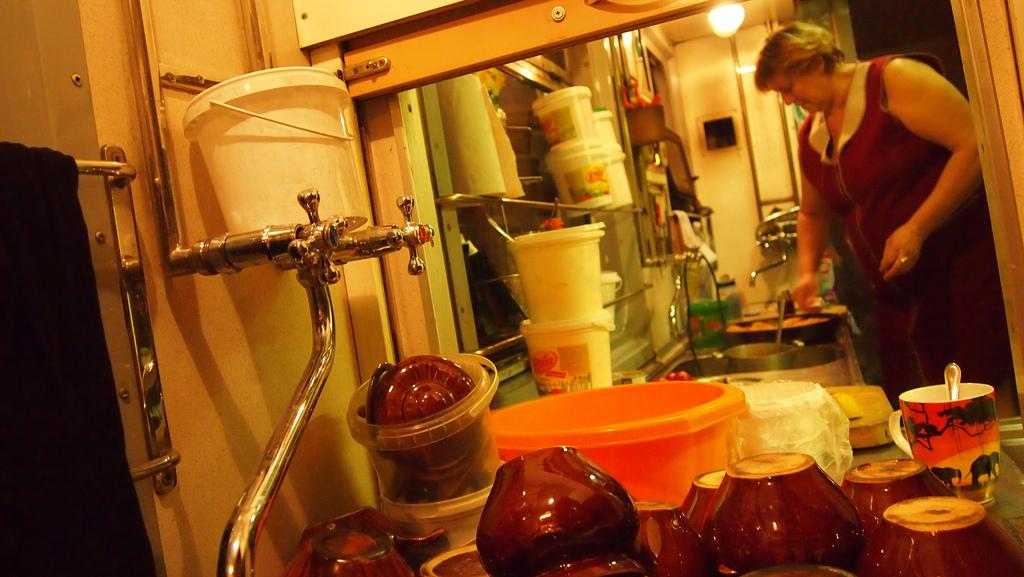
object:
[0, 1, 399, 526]
wall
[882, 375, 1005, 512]
mug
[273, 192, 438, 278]
faucet knob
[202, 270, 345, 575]
pipe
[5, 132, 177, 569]
towel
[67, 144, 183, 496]
rack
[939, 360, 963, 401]
spoon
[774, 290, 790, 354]
utensil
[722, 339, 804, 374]
pot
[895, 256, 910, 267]
ring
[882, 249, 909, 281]
finger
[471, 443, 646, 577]
cup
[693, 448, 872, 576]
cup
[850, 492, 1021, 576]
cup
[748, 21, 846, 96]
hair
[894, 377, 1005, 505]
coffee mug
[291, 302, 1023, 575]
counter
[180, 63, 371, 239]
bucket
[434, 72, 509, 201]
paper towel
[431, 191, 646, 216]
shelf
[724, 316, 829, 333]
food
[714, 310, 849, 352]
frying pan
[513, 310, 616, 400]
object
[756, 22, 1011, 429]
woman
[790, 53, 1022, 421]
dress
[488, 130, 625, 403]
set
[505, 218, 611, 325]
buckets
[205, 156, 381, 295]
set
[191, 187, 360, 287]
knobs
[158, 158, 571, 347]
set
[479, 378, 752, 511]
plastic bowl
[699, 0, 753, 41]
light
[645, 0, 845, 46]
ceiling